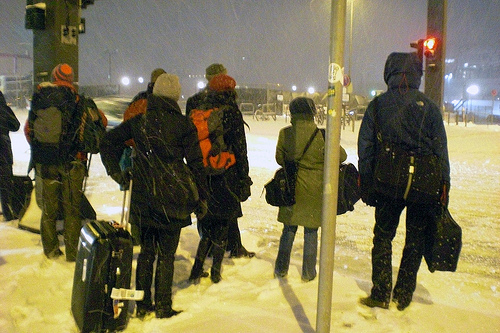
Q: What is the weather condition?
A: It's snowing.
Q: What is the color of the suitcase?
A: Black.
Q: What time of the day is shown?
A: It is nighttime.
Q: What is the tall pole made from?
A: Metal.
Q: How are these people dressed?
A: For cold weather.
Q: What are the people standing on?
A: Snow.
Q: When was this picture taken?
A: At night.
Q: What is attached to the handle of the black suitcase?
A: A flight label.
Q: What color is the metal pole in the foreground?
A: Grey.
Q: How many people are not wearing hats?
A: Zero.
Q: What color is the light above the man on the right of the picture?
A: Red.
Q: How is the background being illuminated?
A: With many bright lights.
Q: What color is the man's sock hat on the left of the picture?
A: Orange and black.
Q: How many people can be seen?
A: 8.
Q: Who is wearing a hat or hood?
A: Every person shown.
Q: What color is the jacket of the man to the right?
A: Blue.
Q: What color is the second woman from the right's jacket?
A: Green.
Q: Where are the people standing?
A: In the snow.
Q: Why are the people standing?
A: Waiting for a ride.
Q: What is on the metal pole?
A: Stickers.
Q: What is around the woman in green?
A: Bag.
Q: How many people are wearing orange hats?
A: 2.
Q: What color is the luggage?
A: Black.